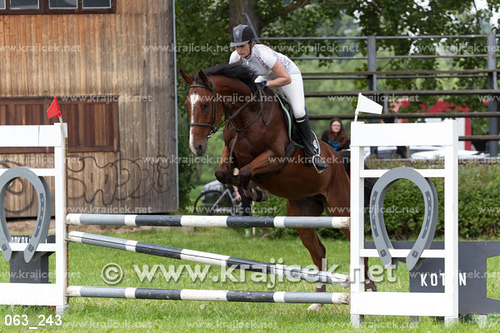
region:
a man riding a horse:
[132, 13, 497, 314]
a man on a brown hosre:
[126, 23, 421, 305]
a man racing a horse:
[158, 14, 458, 284]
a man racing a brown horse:
[152, 23, 484, 278]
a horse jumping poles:
[134, 31, 431, 322]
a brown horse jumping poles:
[128, 23, 445, 327]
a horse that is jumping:
[109, 36, 455, 328]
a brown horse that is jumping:
[133, 16, 425, 319]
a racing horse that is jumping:
[135, 8, 410, 245]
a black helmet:
[222, 23, 259, 50]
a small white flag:
[353, 90, 390, 120]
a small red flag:
[42, 93, 64, 121]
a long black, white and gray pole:
[65, 201, 347, 233]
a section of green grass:
[0, 223, 497, 331]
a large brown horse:
[176, 60, 387, 292]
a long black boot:
[294, 113, 332, 172]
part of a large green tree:
[180, 1, 499, 204]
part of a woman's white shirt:
[228, 45, 280, 82]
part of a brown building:
[0, 0, 181, 215]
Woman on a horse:
[178, 21, 378, 294]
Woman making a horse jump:
[176, 20, 381, 292]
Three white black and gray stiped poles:
[64, 208, 351, 312]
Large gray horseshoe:
[369, 165, 439, 269]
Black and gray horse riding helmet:
[227, 21, 254, 61]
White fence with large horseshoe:
[1, 118, 68, 318]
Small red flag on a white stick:
[44, 93, 66, 134]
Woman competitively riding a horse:
[184, 23, 379, 312]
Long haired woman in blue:
[320, 118, 348, 151]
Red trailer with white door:
[376, 98, 470, 158]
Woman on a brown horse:
[184, 21, 386, 311]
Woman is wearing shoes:
[288, 112, 330, 172]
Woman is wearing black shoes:
[288, 108, 328, 172]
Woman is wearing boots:
[290, 109, 330, 172]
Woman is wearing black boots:
[290, 112, 335, 170]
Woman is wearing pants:
[259, 69, 308, 120]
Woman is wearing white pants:
[261, 72, 308, 121]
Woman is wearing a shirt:
[225, 47, 310, 79]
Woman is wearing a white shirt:
[227, 47, 304, 79]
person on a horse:
[173, 17, 355, 277]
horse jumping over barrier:
[123, 19, 383, 304]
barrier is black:
[78, 203, 349, 311]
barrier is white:
[85, 204, 360, 318]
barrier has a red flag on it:
[27, 80, 82, 160]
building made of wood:
[1, 2, 202, 248]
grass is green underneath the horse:
[80, 252, 368, 329]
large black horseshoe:
[355, 148, 451, 288]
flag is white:
[330, 81, 415, 157]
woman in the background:
[312, 104, 364, 166]